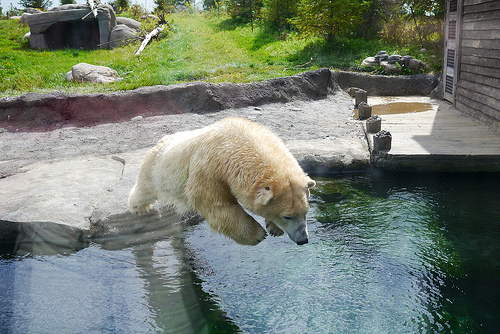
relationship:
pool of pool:
[4, 76, 499, 332] [0, 155, 498, 332]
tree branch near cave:
[135, 24, 166, 60] [18, 2, 148, 54]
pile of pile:
[106, 8, 163, 51] [106, 8, 163, 59]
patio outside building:
[351, 5, 498, 155] [443, 3, 499, 143]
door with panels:
[440, 2, 463, 105] [448, 20, 459, 37]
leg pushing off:
[124, 135, 172, 213] [128, 181, 214, 232]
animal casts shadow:
[124, 116, 319, 246] [126, 229, 244, 334]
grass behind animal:
[2, 16, 362, 92] [124, 116, 319, 246]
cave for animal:
[18, 2, 148, 54] [124, 116, 319, 246]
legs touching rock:
[124, 135, 172, 213] [59, 156, 205, 243]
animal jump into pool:
[124, 116, 319, 246] [0, 155, 498, 332]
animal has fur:
[124, 116, 319, 246] [192, 135, 315, 249]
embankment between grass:
[3, 67, 342, 117] [4, 3, 442, 83]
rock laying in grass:
[60, 61, 126, 86] [0, 8, 366, 93]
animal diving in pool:
[124, 116, 319, 246] [0, 155, 498, 332]